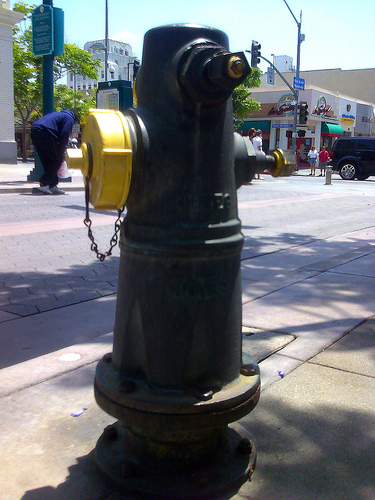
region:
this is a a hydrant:
[79, 24, 249, 418]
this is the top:
[147, 18, 234, 106]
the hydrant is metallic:
[144, 212, 232, 336]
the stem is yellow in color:
[82, 103, 132, 209]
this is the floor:
[7, 253, 76, 347]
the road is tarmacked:
[292, 177, 352, 243]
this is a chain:
[76, 211, 126, 266]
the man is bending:
[39, 99, 74, 180]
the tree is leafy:
[70, 47, 94, 69]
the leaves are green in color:
[71, 50, 88, 73]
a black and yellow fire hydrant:
[73, 32, 294, 408]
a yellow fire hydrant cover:
[69, 101, 138, 217]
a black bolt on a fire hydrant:
[121, 375, 138, 395]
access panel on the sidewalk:
[233, 327, 302, 362]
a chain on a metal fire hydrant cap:
[72, 113, 127, 265]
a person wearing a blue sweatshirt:
[31, 91, 80, 140]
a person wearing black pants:
[27, 129, 62, 183]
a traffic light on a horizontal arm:
[248, 36, 270, 71]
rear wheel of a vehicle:
[338, 159, 356, 179]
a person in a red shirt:
[317, 144, 327, 167]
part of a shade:
[303, 428, 319, 448]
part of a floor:
[311, 422, 328, 449]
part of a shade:
[278, 420, 297, 445]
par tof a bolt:
[195, 471, 218, 498]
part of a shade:
[314, 409, 344, 447]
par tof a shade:
[293, 404, 322, 443]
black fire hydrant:
[75, 14, 269, 495]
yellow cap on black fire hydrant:
[72, 104, 130, 222]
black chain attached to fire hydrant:
[77, 179, 127, 261]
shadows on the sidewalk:
[26, 308, 363, 497]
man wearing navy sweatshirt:
[23, 106, 81, 193]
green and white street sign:
[26, 4, 64, 56]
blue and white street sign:
[287, 75, 306, 91]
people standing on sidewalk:
[304, 143, 329, 171]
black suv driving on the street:
[327, 137, 371, 179]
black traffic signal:
[248, 36, 265, 68]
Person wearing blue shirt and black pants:
[34, 107, 74, 192]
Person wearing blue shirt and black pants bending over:
[30, 90, 87, 196]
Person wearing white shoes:
[33, 102, 82, 203]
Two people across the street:
[300, 141, 330, 171]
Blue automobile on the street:
[326, 135, 371, 173]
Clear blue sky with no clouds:
[311, 9, 345, 49]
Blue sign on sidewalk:
[22, 0, 52, 172]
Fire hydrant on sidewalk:
[60, 12, 315, 488]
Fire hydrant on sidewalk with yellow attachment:
[87, 13, 272, 498]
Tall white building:
[69, 36, 135, 100]